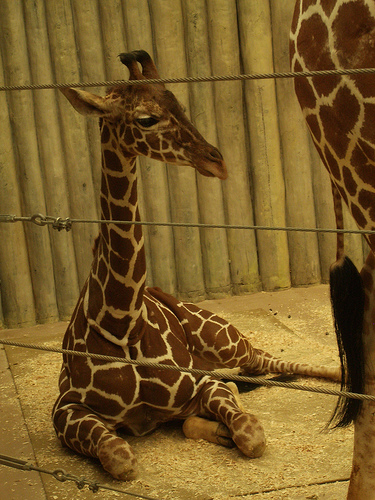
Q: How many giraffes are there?
A: 1.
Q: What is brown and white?
A: The giraffe.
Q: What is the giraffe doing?
A: Laying down.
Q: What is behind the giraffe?
A: A wall.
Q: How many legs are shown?
A: Four.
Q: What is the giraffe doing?
A: Being still.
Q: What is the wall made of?
A: Wood.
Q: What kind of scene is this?
A: Zoo.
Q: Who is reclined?
A: The giraffe.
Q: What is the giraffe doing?
A: Laying down.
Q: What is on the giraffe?
A: Spots.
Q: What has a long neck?
A: The giraffe.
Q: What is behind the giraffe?
A: Wooden poles.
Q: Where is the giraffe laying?
A: On the ground.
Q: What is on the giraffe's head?
A: Horns.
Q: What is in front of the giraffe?
A: Wire fence.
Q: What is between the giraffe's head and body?
A: A neck.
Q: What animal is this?
A: Giraffe.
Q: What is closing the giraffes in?
A: Cable wires.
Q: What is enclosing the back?
A: Wooden wall.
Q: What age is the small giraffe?
A: Baby.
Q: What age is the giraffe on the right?
A: Adult.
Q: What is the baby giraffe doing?
A: Sitting.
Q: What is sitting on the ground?
A: Baby giraffe.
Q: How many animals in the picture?
A: Two.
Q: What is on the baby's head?
A: Horns.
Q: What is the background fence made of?
A: Wood.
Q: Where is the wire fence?
A: Foreground.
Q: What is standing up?
A: Giraffe.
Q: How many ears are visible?
A: One.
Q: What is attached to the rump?
A: Tail.